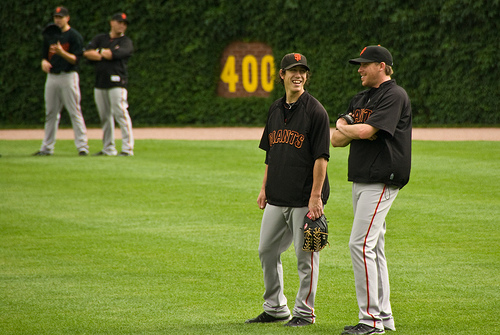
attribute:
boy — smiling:
[283, 66, 307, 91]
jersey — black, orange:
[40, 23, 84, 72]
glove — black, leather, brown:
[303, 212, 329, 250]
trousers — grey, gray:
[41, 72, 91, 151]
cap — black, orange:
[348, 45, 395, 66]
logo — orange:
[291, 52, 304, 63]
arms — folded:
[83, 45, 124, 64]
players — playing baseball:
[32, 4, 408, 335]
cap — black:
[109, 11, 133, 25]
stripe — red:
[70, 73, 85, 130]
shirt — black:
[86, 30, 134, 87]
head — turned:
[106, 12, 132, 40]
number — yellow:
[219, 53, 275, 94]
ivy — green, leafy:
[1, 1, 500, 128]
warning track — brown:
[1, 127, 500, 140]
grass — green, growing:
[1, 139, 499, 334]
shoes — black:
[245, 310, 312, 329]